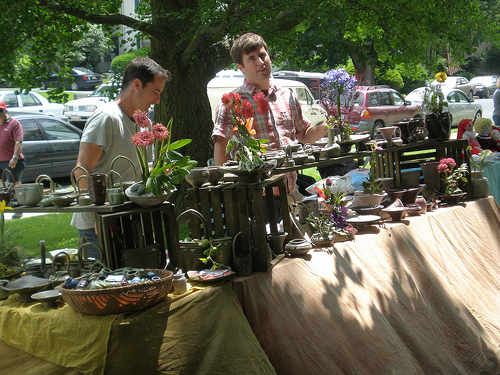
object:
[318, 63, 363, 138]
flower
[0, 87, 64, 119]
car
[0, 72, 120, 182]
parking lot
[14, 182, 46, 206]
gray vase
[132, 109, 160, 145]
flower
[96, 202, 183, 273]
box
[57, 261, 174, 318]
basket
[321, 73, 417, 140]
car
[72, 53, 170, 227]
man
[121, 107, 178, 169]
flowers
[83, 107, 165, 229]
shirt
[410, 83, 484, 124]
car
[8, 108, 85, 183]
car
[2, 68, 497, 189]
parking lot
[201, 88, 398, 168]
flowers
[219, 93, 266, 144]
flower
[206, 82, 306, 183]
shirt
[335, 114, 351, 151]
stem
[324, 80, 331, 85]
flowers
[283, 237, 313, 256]
vase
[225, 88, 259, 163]
flowers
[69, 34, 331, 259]
men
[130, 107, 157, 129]
flower top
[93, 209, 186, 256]
drawer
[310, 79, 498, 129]
parking lot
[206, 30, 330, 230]
man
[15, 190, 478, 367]
table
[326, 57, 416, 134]
parking